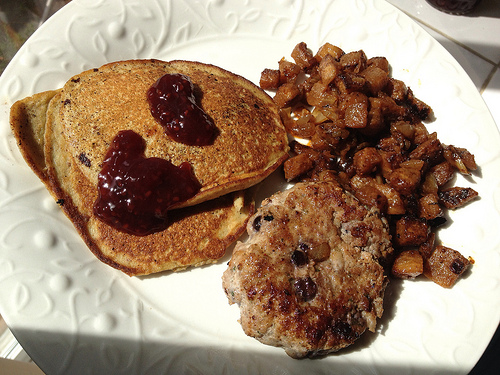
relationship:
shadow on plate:
[13, 328, 449, 374] [0, 0, 499, 373]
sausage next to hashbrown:
[231, 183, 390, 359] [335, 85, 370, 130]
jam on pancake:
[143, 74, 220, 145] [60, 53, 288, 202]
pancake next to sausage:
[60, 53, 288, 202] [231, 183, 390, 359]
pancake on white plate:
[60, 53, 288, 202] [0, 0, 499, 373]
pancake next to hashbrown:
[60, 53, 288, 202] [335, 85, 370, 130]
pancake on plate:
[60, 53, 288, 202] [0, 0, 499, 373]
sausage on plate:
[231, 183, 390, 359] [0, 0, 499, 373]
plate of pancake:
[0, 0, 499, 373] [60, 53, 288, 202]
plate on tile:
[0, 0, 499, 373] [395, 10, 496, 93]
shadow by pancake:
[13, 328, 449, 374] [60, 53, 288, 202]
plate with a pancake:
[0, 0, 499, 373] [60, 53, 288, 202]